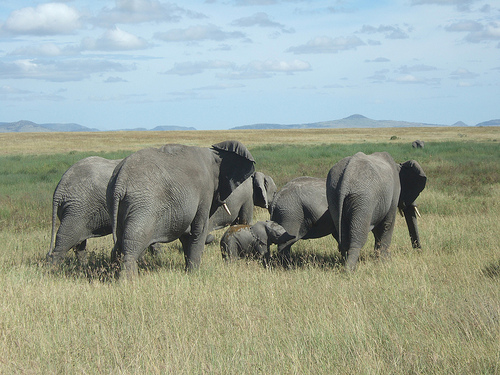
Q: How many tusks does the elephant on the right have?
A: Two.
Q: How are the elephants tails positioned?
A: Down.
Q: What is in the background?
A: Mountains.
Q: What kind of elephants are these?
A: African.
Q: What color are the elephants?
A: Gray.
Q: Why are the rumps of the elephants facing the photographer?
A: They are walking away.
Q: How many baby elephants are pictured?
A: One.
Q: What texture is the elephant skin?
A: Wrinkled.